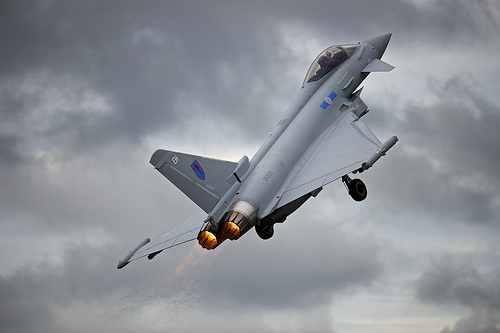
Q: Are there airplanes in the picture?
A: Yes, there is an airplane.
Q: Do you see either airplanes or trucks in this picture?
A: Yes, there is an airplane.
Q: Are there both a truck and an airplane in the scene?
A: No, there is an airplane but no trucks.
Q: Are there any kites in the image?
A: No, there are no kites.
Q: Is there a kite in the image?
A: No, there are no kites.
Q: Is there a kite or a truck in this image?
A: No, there are no kites or trucks.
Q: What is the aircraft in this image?
A: The aircraft is an airplane.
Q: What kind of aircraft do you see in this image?
A: The aircraft is an airplane.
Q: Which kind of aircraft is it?
A: The aircraft is an airplane.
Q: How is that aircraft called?
A: This is an airplane.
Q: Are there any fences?
A: No, there are no fences.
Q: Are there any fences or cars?
A: No, there are no fences or cars.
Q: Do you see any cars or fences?
A: No, there are no fences or cars.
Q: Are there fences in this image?
A: No, there are no fences.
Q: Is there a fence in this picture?
A: No, there are no fences.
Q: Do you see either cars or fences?
A: No, there are no fences or cars.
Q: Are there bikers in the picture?
A: No, there are no bikers.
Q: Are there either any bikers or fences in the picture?
A: No, there are no bikers or fences.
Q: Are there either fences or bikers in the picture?
A: No, there are no bikers or fences.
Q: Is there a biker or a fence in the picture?
A: No, there are no bikers or fences.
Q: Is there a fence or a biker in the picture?
A: No, there are no bikers or fences.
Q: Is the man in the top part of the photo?
A: Yes, the man is in the top of the image.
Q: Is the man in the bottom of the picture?
A: No, the man is in the top of the image.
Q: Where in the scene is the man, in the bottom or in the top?
A: The man is in the top of the image.